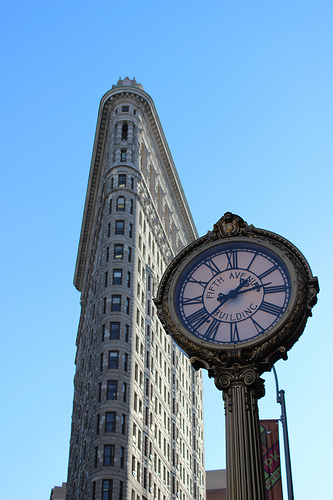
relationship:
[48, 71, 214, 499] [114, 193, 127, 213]
building has window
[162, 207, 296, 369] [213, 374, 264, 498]
clock on pole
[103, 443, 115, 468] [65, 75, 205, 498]
window of  a building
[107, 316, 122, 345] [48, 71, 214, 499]
window of a building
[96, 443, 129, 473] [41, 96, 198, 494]
window of building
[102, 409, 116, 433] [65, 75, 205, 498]
window of a building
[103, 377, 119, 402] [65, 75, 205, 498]
window of a building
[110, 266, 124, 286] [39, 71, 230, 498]
window of a building